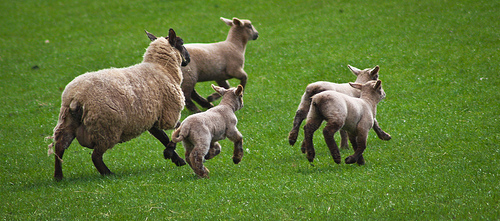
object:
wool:
[85, 72, 163, 124]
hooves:
[342, 155, 359, 166]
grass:
[0, 0, 499, 220]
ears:
[165, 27, 179, 42]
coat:
[49, 36, 187, 155]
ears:
[371, 79, 384, 90]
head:
[218, 14, 262, 40]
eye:
[243, 22, 253, 30]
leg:
[320, 116, 345, 159]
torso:
[180, 102, 245, 179]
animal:
[167, 83, 245, 180]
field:
[0, 0, 499, 220]